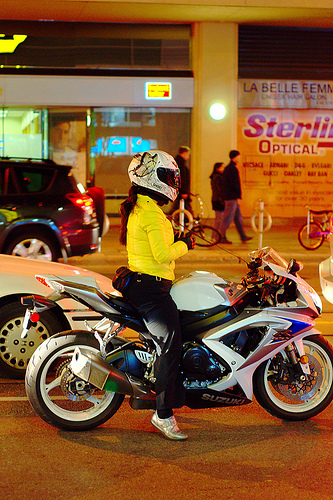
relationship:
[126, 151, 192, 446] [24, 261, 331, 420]
girl riding on motorcycle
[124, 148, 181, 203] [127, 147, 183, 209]
helmet on top of head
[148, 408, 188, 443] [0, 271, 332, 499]
shoe touching street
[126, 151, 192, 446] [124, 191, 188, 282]
girl wearing jacket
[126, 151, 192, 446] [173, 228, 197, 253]
girl wearing gloves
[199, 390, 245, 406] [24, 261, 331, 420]
company name on side of motorcycle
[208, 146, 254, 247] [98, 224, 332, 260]
couple walking on sidewalk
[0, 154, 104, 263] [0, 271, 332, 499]
suv driving down street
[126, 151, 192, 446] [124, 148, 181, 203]
girl wearing helmet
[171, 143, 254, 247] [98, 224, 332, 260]
people walking on sidewalk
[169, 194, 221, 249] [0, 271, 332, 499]
bicycle parked on side of street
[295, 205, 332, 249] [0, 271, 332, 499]
bicycle parked on side of street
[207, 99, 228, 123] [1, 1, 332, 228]
light on front of building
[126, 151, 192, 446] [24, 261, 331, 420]
girl riding motorcycle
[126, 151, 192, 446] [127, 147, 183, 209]
girl has head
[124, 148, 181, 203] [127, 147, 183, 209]
helmet covering head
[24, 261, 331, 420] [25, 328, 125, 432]
motorcycle has tire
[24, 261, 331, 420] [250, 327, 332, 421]
motorcycle has tire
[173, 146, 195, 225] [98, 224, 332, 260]
man walking on sidewalk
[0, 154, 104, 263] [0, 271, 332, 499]
suv driving on street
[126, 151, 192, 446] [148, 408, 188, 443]
girl wearing shoe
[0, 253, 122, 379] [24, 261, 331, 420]
car riding behind motorcycle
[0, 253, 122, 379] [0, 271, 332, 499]
car riding on street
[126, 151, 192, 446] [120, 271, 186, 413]
girl wearing pants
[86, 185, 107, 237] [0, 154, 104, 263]
spare tire on back of suv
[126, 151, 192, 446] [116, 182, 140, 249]
girl has ponytail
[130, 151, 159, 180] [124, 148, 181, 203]
butterfly on side of helmet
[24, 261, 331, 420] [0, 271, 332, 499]
motorcycle sitting on street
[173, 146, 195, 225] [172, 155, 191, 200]
man wearing jacket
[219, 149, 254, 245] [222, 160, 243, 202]
man wearing jacket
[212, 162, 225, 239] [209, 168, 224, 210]
people wearing jacket